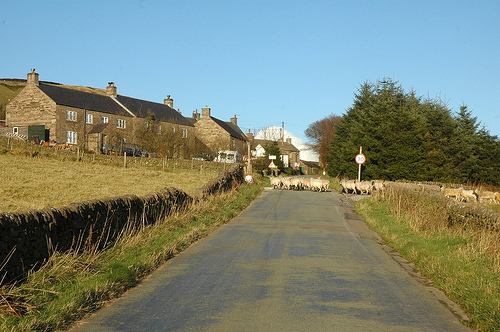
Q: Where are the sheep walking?
A: Towards the house.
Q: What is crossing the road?
A: Sheep.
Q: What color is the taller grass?
A: Yellow.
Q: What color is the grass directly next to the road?
A: Green.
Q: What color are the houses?
A: Brown.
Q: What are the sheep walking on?
A: The road.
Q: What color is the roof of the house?
A: Black.